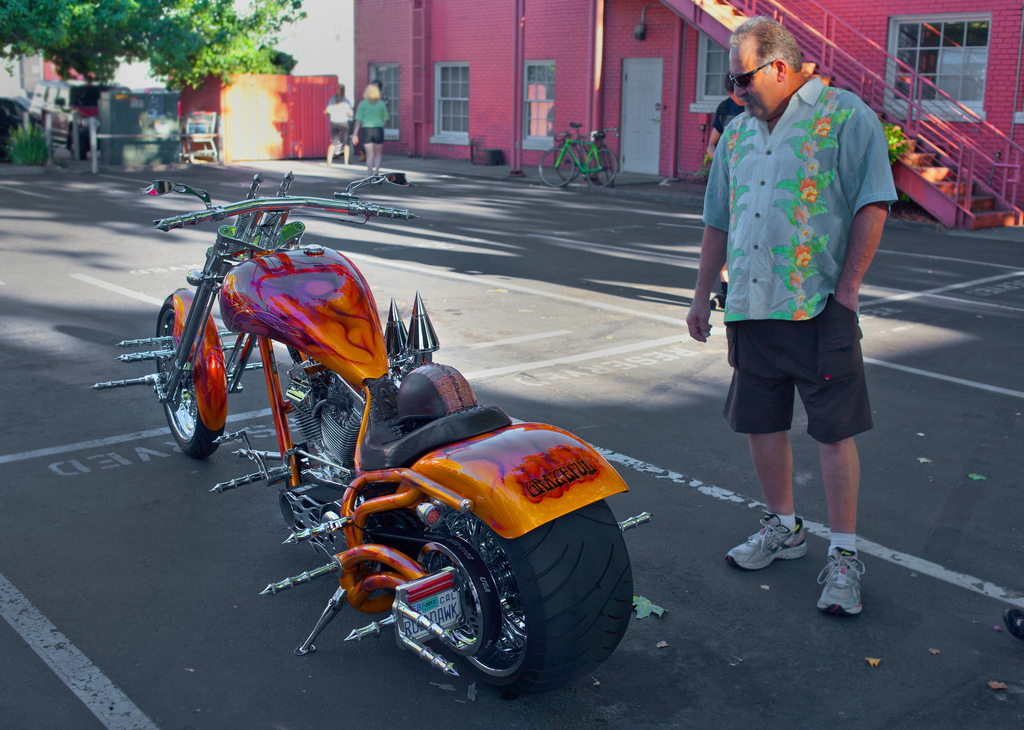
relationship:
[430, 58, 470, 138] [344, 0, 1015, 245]
window on building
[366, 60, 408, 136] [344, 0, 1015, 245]
window on building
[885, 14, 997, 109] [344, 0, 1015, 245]
window on building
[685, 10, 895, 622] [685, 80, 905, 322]
man wearing shirt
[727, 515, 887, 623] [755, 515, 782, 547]
shoes with laces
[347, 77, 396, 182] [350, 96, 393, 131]
person in shirt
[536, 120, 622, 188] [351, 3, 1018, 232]
bicycle against wall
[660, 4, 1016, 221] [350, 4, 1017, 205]
staircase outside building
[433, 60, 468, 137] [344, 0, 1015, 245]
window on a building